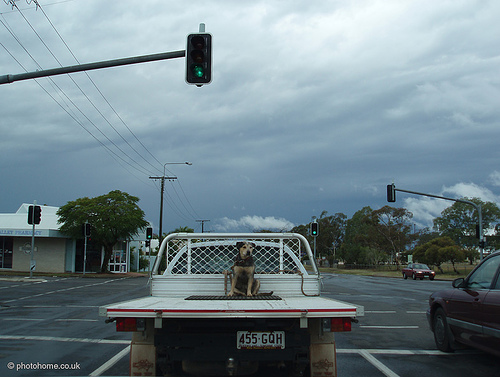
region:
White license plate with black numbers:
[231, 325, 288, 350]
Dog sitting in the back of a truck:
[220, 235, 280, 302]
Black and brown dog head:
[232, 236, 259, 261]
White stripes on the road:
[345, 345, 443, 375]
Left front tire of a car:
[430, 310, 452, 353]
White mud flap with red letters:
[127, 339, 157, 373]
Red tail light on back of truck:
[327, 317, 353, 332]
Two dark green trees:
[54, 188, 150, 278]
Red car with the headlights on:
[398, 258, 436, 281]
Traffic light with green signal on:
[144, 225, 154, 242]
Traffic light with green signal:
[184, 20, 214, 88]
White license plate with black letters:
[232, 323, 290, 352]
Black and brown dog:
[225, 239, 261, 301]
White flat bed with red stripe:
[100, 290, 364, 320]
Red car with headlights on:
[399, 258, 438, 282]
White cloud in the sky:
[205, 210, 294, 232]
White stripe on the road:
[5, 329, 130, 353]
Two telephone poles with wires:
[150, 173, 212, 234]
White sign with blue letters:
[0, 225, 50, 236]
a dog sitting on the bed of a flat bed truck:
[228, 235, 263, 295]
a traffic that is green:
[178, 27, 222, 89]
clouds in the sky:
[356, 75, 458, 141]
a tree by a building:
[54, 185, 146, 277]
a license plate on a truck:
[236, 327, 290, 350]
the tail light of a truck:
[325, 313, 355, 335]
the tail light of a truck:
[113, 313, 148, 336]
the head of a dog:
[234, 236, 261, 261]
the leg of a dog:
[243, 267, 255, 302]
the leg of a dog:
[227, 268, 238, 297]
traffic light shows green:
[175, 32, 226, 91]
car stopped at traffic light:
[397, 249, 441, 279]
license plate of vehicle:
[226, 327, 295, 347]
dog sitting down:
[223, 237, 273, 299]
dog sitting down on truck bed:
[211, 236, 283, 318]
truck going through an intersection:
[101, 217, 361, 375]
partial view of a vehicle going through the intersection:
[428, 247, 498, 347]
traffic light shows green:
[303, 214, 326, 236]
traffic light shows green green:
[141, 213, 156, 239]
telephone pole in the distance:
[155, 153, 172, 235]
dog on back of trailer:
[219, 245, 275, 287]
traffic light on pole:
[376, 180, 408, 211]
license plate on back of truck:
[230, 326, 288, 369]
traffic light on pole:
[21, 203, 43, 233]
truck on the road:
[97, 208, 342, 365]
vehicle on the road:
[389, 252, 434, 282]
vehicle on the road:
[407, 235, 499, 357]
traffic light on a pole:
[308, 221, 323, 231]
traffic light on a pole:
[143, 228, 152, 241]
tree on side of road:
[80, 189, 129, 270]